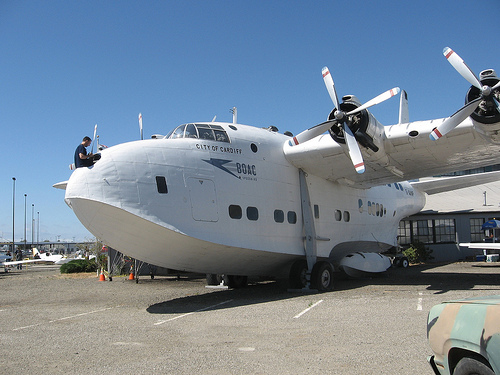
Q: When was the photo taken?
A: Daytime.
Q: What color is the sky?
A: Blue.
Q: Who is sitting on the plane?
A: A man.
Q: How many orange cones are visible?
A: Two.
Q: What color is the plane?
A: White.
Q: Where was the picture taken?
A: On an airport.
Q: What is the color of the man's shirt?
A: Black.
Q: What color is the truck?
A: Black, brown and green.